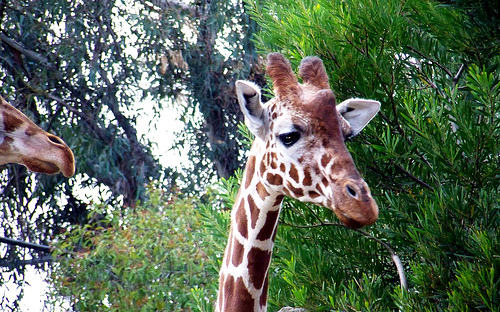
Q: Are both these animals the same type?
A: Yes, all the animals are giraffes.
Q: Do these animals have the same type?
A: Yes, all the animals are giraffes.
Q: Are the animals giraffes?
A: Yes, all the animals are giraffes.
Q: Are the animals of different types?
A: No, all the animals are giraffes.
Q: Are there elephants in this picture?
A: No, there are no elephants.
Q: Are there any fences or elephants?
A: No, there are no elephants or fences.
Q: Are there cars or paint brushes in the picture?
A: No, there are no cars or paint brushes.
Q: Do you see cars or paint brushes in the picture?
A: No, there are no cars or paint brushes.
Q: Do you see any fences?
A: No, there are no fences.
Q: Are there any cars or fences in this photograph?
A: No, there are no fences or cars.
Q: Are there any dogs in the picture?
A: No, there are no dogs.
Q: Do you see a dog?
A: No, there are no dogs.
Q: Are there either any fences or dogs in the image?
A: No, there are no dogs or fences.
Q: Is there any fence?
A: No, there are no fences.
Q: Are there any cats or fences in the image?
A: No, there are no fences or cats.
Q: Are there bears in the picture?
A: No, there are no bears.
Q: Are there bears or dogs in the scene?
A: No, there are no bears or dogs.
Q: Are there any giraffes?
A: Yes, there is a giraffe.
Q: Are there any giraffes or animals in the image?
A: Yes, there is a giraffe.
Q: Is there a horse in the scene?
A: No, there are no horses.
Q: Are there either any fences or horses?
A: No, there are no horses or fences.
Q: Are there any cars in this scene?
A: No, there are no cars.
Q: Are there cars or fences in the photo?
A: No, there are no cars or fences.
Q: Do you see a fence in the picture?
A: No, there are no fences.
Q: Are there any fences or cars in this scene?
A: No, there are no fences or cars.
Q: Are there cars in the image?
A: No, there are no cars.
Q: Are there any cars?
A: No, there are no cars.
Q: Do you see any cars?
A: No, there are no cars.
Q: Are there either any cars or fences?
A: No, there are no cars or fences.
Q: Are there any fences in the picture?
A: No, there are no fences.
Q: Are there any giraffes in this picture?
A: Yes, there is a giraffe.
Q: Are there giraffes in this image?
A: Yes, there is a giraffe.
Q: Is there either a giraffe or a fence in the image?
A: Yes, there is a giraffe.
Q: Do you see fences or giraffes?
A: Yes, there is a giraffe.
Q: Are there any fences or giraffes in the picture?
A: Yes, there is a giraffe.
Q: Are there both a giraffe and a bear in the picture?
A: No, there is a giraffe but no bears.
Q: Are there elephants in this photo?
A: No, there are no elephants.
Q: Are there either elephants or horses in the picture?
A: No, there are no elephants or horses.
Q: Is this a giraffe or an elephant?
A: This is a giraffe.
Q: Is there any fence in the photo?
A: No, there are no fences.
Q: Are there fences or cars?
A: No, there are no fences or cars.